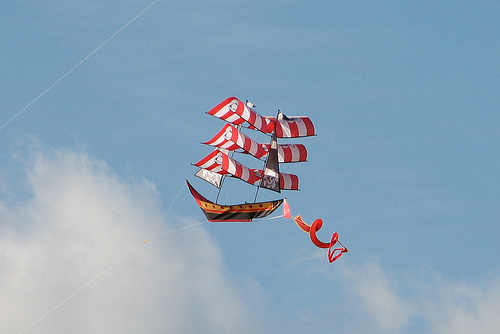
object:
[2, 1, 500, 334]
sky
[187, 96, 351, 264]
kite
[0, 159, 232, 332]
cloud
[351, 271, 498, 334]
cloud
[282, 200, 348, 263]
tail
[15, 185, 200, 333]
string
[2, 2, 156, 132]
string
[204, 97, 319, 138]
top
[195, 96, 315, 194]
sails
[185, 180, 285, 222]
ship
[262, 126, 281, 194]
flag